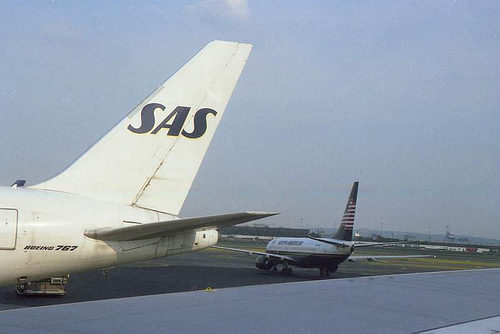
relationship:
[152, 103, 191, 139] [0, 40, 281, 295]
letter a on airplane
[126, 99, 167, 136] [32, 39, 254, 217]
letter s on tail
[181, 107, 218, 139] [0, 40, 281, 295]
letter s on airplane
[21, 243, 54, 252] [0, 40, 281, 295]
word on side of a airplane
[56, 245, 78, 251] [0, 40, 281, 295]
767 on side of a airplane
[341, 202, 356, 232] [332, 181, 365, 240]
flag on tail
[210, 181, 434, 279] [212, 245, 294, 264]
airplane has a left wing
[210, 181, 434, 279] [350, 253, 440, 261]
airplane has a right wing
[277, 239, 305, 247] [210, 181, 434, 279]
letters are on side of a airplane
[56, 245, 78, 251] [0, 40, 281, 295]
767 written on airplane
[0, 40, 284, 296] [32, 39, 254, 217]
airplane has a tail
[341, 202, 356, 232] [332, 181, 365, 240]
flag painted on tail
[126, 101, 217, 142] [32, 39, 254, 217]
writing on tail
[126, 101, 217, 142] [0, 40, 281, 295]
writing on rear of airplane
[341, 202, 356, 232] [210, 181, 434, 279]
flag on airplane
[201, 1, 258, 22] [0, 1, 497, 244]
cloud in sky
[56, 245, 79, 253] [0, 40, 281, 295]
767 on side of a airplane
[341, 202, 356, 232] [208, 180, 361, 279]
flag on airplane